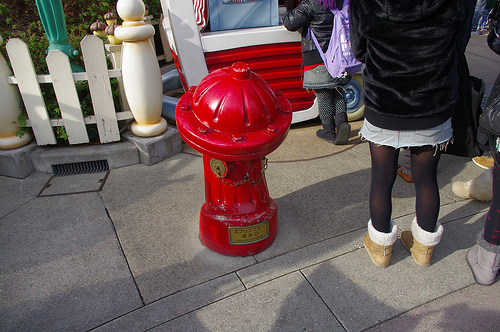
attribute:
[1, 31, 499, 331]
sidewalk — cement, grey, floor, partial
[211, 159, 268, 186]
chain — metal, partial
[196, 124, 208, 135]
bolt — partial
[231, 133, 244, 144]
bolt — partial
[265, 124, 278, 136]
bolt — partial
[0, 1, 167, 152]
fence — wood, white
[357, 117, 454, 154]
skirt — jean, short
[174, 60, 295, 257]
fire hydrant — red, shiny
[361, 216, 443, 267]
boots — tan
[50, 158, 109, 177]
grate — metal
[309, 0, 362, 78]
backpack — purple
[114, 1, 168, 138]
fence pole — white, fat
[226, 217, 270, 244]
plate — metal, gold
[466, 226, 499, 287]
boot — grey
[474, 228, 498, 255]
fleece lining — dark grey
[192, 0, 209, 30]
lines — red, white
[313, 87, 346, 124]
stockings — partial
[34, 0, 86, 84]
pole — green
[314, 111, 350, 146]
uggs — black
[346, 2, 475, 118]
jacket — black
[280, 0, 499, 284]
people — lined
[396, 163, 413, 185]
shoe — partial, edge